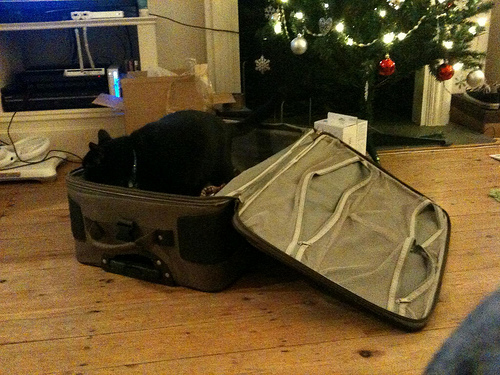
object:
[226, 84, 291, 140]
tail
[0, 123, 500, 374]
floor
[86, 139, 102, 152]
ears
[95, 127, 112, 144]
ear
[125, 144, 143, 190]
collar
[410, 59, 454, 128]
package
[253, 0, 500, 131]
christmas tree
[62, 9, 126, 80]
entertainment device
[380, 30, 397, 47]
light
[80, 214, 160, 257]
handle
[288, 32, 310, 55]
ornament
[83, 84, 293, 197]
cat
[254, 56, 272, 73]
star shape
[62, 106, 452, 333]
luggage case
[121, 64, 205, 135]
open box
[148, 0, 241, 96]
wall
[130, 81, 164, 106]
brown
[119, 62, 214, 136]
box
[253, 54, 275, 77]
section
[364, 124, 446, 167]
base